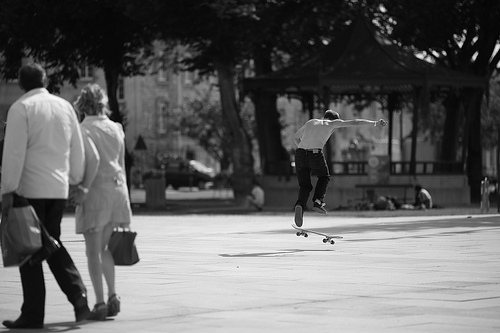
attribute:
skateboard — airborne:
[287, 219, 344, 243]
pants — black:
[4, 188, 94, 319]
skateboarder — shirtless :
[235, 77, 409, 270]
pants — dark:
[297, 147, 332, 227]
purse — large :
[107, 223, 140, 267]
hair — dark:
[17, 62, 44, 91]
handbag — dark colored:
[98, 214, 165, 286]